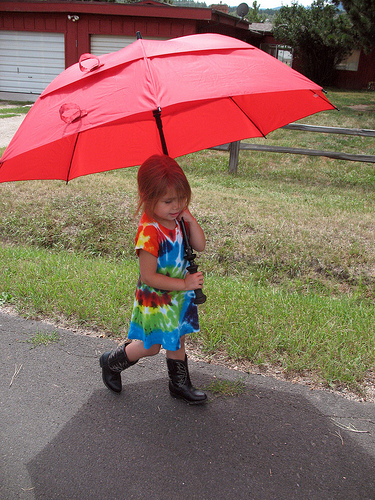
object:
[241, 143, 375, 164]
post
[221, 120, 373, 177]
fence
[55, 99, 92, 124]
red loop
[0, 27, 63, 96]
white doors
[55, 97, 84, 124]
straps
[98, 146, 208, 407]
girl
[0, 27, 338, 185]
umbrella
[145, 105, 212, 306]
umbrella handle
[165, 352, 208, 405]
shoe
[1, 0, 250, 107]
building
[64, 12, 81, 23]
light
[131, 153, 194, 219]
hair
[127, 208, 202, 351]
dress